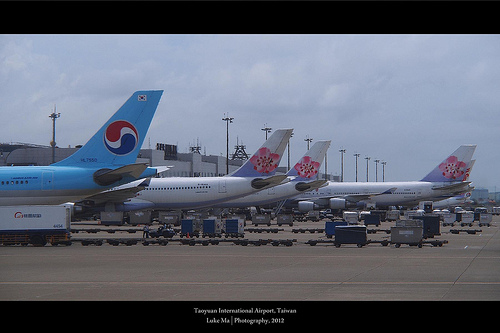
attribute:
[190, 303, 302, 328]
text — white, black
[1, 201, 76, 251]
service vehicle — white, gray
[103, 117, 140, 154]
logo — red, white, blue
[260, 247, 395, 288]
concrete — black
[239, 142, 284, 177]
flower — pink, logo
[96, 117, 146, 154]
swirl — red, white, and blue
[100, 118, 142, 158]
logo — Airline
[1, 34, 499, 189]
sky — blue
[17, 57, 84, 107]
clouds — white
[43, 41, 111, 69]
sky — blue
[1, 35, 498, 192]
skies — cloudy, white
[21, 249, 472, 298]
pavement — gray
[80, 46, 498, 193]
sky — blue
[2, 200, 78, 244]
truck — white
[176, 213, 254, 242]
luggage carts — three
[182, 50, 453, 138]
clouds — white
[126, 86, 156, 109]
flag — South Korean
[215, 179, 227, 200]
door — rear, emergency exit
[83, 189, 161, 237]
engine — blue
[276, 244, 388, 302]
line — yellow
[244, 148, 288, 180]
flower — pink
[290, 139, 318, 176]
flower — pink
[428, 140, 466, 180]
flower — pink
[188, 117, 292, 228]
planes — white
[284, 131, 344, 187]
planes — white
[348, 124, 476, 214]
planes — white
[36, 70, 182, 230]
plane — blue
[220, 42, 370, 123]
clouds — white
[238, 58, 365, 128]
clouds — white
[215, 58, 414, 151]
sky — blue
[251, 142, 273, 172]
flower — pink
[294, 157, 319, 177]
flower — pink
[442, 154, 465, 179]
flower — pink